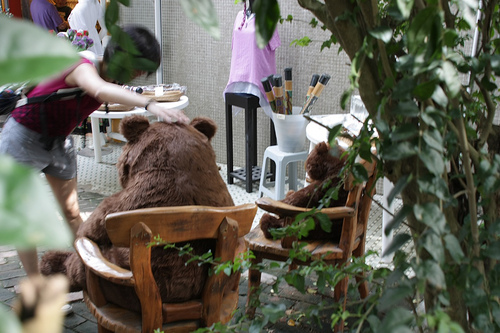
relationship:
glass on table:
[350, 94, 371, 126] [306, 113, 395, 256]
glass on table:
[350, 94, 371, 126] [89, 86, 189, 164]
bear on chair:
[260, 141, 361, 242] [246, 153, 372, 330]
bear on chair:
[38, 111, 246, 329] [72, 200, 256, 330]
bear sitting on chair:
[260, 141, 361, 242] [246, 153, 372, 330]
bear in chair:
[275, 126, 361, 273] [247, 174, 383, 283]